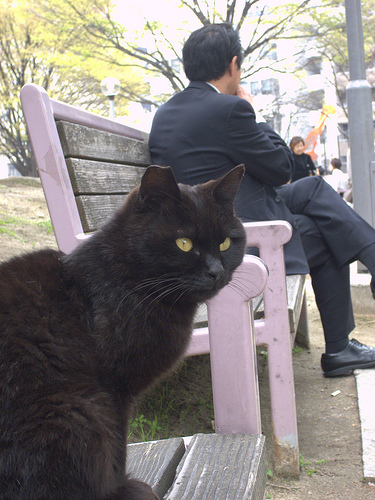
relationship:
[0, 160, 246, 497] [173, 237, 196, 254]
cat has eye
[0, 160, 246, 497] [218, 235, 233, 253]
cat has eye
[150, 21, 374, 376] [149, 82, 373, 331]
man wearing a suit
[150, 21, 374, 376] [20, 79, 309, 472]
man sitting on bench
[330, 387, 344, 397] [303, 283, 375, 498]
cigarette butt on ground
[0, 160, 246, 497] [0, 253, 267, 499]
cat sitting on a bench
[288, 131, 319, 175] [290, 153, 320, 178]
woman wearing a coat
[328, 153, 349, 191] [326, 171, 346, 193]
woman wearing a coat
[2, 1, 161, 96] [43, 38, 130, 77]
tree has leaves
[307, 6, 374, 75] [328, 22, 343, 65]
tree has leaves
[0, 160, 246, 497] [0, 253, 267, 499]
cat sitting on bench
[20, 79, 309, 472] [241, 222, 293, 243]
bench has arm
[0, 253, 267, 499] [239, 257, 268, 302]
bench has arm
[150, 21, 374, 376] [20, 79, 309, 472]
man sitting on a bench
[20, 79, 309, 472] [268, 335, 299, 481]
bench has a leg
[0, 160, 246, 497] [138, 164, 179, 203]
cat has an ear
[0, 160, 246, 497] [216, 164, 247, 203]
cat has an ear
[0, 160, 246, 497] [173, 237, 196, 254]
cat has an eye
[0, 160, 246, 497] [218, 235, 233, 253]
cat has an eye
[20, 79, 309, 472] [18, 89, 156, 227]
bench has a back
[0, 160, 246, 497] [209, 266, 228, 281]
cat has a nose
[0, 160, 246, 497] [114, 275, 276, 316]
cat has whiskers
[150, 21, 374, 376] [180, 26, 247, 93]
man has a head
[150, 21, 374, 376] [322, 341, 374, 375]
man wearing shoe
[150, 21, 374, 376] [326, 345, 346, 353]
man wearing socks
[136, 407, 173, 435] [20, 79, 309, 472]
grass under bench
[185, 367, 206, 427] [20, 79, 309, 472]
dirt under bench